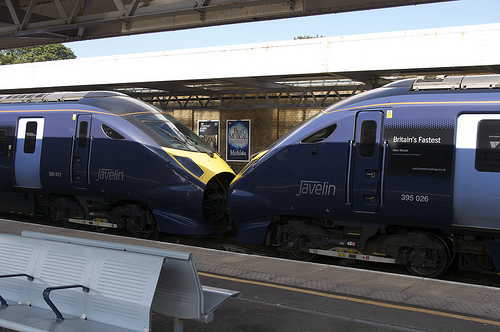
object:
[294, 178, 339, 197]
white sticker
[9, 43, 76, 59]
leaves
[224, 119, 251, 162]
poster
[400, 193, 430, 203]
number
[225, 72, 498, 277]
train engine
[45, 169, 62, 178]
number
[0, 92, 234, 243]
train engine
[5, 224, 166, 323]
metal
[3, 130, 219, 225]
shadow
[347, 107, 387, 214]
door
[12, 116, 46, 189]
door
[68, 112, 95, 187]
door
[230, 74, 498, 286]
train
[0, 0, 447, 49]
metal rafters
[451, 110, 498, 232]
door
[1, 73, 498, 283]
train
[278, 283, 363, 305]
yellow line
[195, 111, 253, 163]
posters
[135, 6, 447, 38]
sky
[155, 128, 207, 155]
windshield wiper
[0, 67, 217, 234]
train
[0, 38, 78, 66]
tree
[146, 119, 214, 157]
wipers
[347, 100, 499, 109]
yellow stripe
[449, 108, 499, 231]
doors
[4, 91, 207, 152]
light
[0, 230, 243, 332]
bench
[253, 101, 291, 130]
wall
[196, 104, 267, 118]
wall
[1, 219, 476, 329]
platform